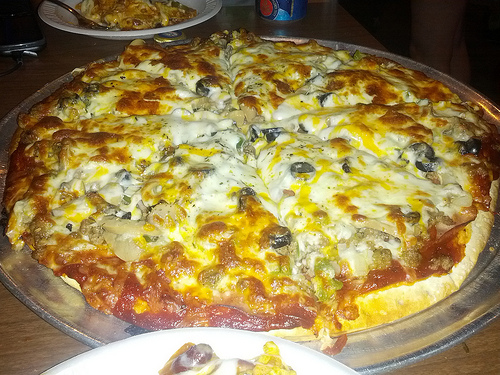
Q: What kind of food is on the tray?
A: Pizza.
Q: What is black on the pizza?
A: Olives.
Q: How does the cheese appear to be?
A: Melted.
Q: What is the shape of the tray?
A: Circle.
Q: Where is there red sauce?
A: On pizza.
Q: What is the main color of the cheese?
A: White.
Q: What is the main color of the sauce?
A: Red.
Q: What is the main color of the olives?
A: Black.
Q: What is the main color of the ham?
A: Pink.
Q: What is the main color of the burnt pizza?
A: Brown.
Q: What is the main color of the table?
A: Brown.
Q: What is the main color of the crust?
A: Brown.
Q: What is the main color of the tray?
A: Grey.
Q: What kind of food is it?
A: A pizza.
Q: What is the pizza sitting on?
A: A table.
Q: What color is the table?
A: Brown.